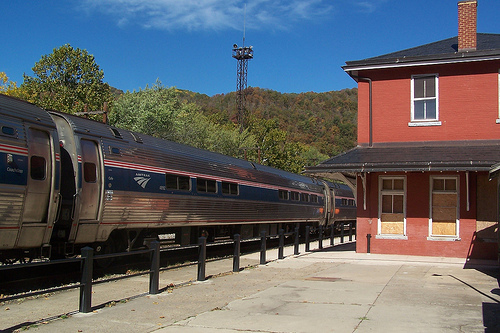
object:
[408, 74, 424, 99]
frame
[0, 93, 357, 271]
train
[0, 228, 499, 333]
station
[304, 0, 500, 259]
building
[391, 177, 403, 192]
windows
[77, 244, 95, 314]
pole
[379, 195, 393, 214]
window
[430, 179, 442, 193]
window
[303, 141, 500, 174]
lower roof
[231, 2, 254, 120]
tower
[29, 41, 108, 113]
tree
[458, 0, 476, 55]
chimney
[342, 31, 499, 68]
roof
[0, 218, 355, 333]
fence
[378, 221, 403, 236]
wood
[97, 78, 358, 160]
hillside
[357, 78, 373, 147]
drain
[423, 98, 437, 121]
window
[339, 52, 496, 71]
gutter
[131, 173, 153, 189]
logo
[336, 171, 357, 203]
corbel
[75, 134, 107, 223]
door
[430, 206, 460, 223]
woods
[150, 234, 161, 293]
post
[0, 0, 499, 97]
sky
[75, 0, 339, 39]
white clouds